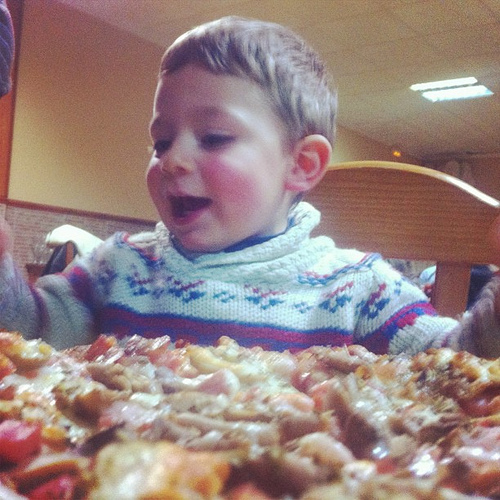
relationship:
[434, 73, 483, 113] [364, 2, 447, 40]
light on ceiling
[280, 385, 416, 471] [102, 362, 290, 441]
toppings on pizza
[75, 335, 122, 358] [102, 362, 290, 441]
tomatoes on pizza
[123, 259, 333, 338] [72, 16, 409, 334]
sweater on boy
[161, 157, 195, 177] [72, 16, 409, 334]
nose of boy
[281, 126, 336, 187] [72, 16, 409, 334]
ear of boy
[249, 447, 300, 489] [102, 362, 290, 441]
sausage on pizza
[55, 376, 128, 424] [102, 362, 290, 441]
peppers on pizza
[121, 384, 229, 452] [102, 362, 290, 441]
cheese on pizza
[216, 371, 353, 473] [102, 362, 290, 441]
onions on pizza